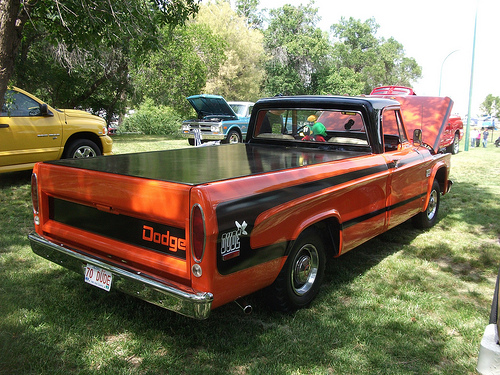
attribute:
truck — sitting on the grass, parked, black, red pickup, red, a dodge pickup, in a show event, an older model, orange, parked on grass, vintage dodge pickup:
[28, 94, 456, 327]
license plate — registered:
[84, 262, 114, 293]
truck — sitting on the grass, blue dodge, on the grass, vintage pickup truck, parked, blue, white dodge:
[180, 93, 302, 146]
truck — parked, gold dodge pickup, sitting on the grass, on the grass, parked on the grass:
[0, 83, 114, 181]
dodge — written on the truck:
[141, 223, 188, 253]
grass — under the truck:
[3, 122, 499, 371]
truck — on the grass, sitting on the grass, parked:
[366, 83, 467, 158]